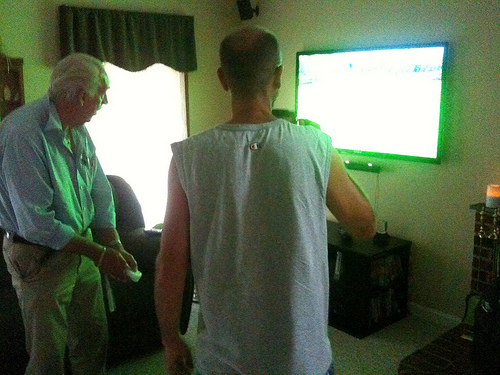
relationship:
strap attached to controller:
[101, 270, 118, 312] [122, 264, 142, 283]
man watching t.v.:
[153, 22, 380, 373] [283, 36, 463, 177]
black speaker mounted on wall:
[232, 1, 267, 18] [195, 2, 498, 314]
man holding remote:
[9, 48, 141, 365] [123, 261, 143, 284]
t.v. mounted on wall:
[293, 38, 449, 165] [244, 0, 493, 312]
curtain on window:
[41, 12, 196, 78] [72, 60, 190, 237]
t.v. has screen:
[293, 38, 449, 165] [296, 45, 443, 158]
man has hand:
[9, 48, 141, 365] [100, 243, 133, 284]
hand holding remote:
[100, 243, 133, 284] [124, 267, 143, 283]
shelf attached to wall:
[1, 59, 31, 99] [0, 0, 66, 111]